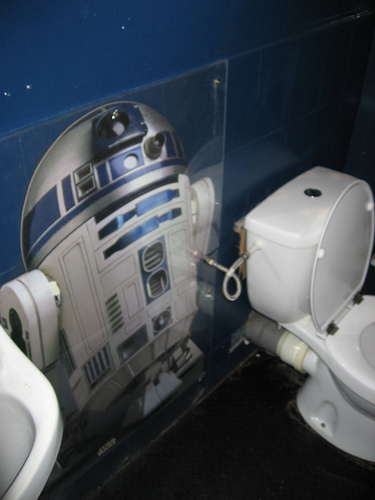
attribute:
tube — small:
[210, 247, 249, 300]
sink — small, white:
[7, 306, 110, 497]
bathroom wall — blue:
[2, 0, 373, 455]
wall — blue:
[36, 22, 319, 123]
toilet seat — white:
[323, 296, 374, 390]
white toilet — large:
[234, 165, 373, 463]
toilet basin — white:
[237, 164, 357, 337]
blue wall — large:
[5, 5, 275, 449]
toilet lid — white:
[310, 179, 373, 331]